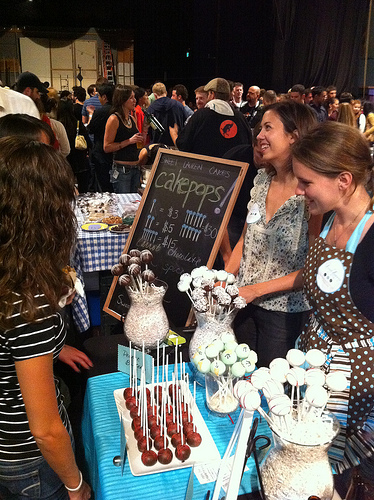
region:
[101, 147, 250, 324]
a chalk board advertising cakepops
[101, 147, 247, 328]
a brown wood trim chalkboard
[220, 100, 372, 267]
two females selling cakepops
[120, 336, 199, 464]
round red velvet cakes on a stick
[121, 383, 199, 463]
round red velvet cakes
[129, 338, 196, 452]
white sticks in the round red velvet cakes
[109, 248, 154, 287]
chocolate round cakepops on sticks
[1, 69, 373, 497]
people inside a venue at a food event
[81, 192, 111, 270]
food on the table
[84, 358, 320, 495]
table with desserts on it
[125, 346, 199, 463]
dessert balls on sticks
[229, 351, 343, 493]
vase with dessert balls on stick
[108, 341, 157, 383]
card with dessert name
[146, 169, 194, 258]
information on a board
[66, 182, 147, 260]
table with items on it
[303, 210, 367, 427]
apron on a woman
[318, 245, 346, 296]
button on the apron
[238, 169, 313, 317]
blouse on the woman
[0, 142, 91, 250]
head of a person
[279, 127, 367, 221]
head of a person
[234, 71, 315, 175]
head of a person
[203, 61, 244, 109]
head of a person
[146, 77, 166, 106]
head of a person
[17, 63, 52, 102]
head of a person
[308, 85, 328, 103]
head of a person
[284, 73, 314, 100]
head of a person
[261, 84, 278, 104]
head of a person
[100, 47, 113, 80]
a ladder against the wall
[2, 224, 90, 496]
a lady wearing a striped shirt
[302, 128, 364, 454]
a lady wearing a brown apron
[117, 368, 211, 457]
cake pops on a plate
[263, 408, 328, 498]
a glass vase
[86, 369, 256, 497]
a blue table cloth on the table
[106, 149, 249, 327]
a chalk board sign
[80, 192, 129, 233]
food sitting on a table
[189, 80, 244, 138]
a man wearing a hat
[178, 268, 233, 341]
cake pops in a vase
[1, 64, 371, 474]
crowd of people socializing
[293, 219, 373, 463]
brown apron with light blue polka dots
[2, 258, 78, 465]
black and white striped shirt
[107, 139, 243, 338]
chalkboard with wood frame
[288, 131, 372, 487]
woman wearing blue and brown apron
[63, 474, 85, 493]
white bracelet on woman's wrist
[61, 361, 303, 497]
blue tablecloth on the table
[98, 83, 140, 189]
woman wearing black tanktop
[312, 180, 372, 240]
blue neck straps on the apron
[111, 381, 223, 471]
white tray on the blue tablecloth